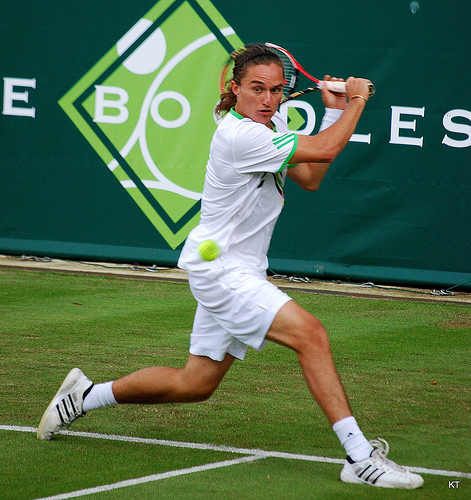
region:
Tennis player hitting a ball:
[20, 28, 458, 499]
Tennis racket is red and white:
[271, 44, 377, 105]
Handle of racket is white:
[314, 72, 381, 100]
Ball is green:
[188, 235, 225, 271]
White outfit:
[172, 99, 309, 373]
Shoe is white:
[333, 453, 428, 497]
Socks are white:
[80, 375, 369, 459]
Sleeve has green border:
[222, 110, 310, 184]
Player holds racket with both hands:
[183, 17, 386, 214]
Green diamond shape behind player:
[47, 0, 212, 251]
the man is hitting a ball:
[163, 214, 366, 393]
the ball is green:
[150, 217, 270, 307]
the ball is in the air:
[178, 224, 291, 301]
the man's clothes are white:
[136, 85, 333, 384]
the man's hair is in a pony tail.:
[199, 26, 293, 143]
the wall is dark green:
[0, 4, 444, 260]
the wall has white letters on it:
[0, 37, 450, 177]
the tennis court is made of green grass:
[2, 264, 434, 489]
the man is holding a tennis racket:
[172, 27, 452, 152]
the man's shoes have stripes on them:
[29, 355, 431, 488]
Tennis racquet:
[209, 49, 412, 96]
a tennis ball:
[148, 220, 249, 259]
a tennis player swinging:
[81, 30, 420, 474]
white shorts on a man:
[155, 266, 314, 352]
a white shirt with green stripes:
[174, 115, 290, 265]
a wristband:
[316, 104, 340, 134]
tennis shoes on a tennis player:
[46, 359, 430, 486]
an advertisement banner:
[17, 11, 187, 251]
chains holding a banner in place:
[281, 269, 462, 293]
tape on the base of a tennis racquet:
[315, 81, 376, 89]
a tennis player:
[38, 27, 467, 499]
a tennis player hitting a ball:
[62, 16, 394, 409]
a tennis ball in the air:
[127, 203, 286, 279]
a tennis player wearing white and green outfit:
[101, 35, 360, 368]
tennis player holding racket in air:
[100, 0, 454, 248]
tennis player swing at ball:
[10, 12, 448, 487]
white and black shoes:
[296, 377, 440, 499]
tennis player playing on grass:
[1, 6, 417, 487]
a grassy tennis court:
[11, 263, 433, 497]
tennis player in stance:
[11, 4, 469, 480]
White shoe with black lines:
[29, 358, 121, 473]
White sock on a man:
[312, 400, 427, 492]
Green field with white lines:
[23, 359, 262, 498]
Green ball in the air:
[185, 228, 255, 276]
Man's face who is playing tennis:
[210, 25, 312, 143]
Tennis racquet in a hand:
[215, 39, 392, 135]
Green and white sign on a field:
[23, 30, 455, 246]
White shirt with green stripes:
[188, 95, 311, 271]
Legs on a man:
[115, 277, 404, 472]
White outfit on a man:
[172, 105, 320, 376]